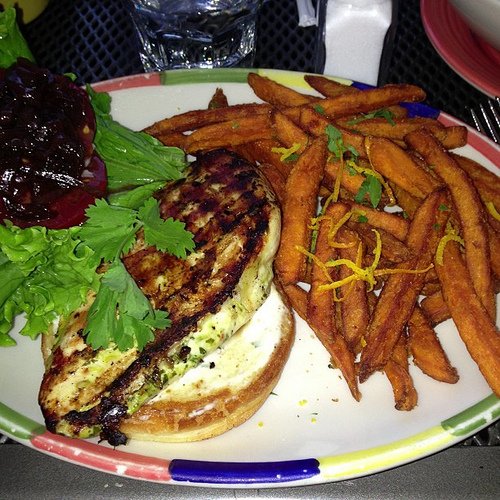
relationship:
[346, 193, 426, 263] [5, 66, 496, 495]
fries on plate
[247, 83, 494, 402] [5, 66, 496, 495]
fries on plate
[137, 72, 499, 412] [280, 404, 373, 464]
fries on plate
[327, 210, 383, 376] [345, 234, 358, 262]
chips seen part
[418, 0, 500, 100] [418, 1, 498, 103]
edge with edge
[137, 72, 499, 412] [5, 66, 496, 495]
fries are on a plate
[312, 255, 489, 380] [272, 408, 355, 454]
fries are on a plate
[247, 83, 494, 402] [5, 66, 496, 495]
fries are on a plate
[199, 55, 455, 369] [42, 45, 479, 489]
fries are on a plate